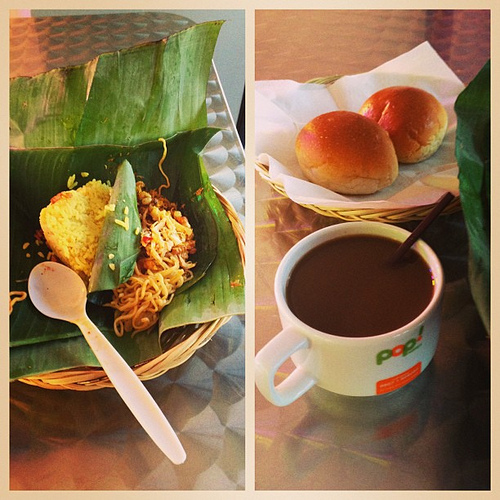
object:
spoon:
[28, 261, 186, 463]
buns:
[293, 109, 399, 196]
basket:
[254, 74, 467, 226]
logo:
[375, 329, 429, 367]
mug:
[258, 221, 444, 411]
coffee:
[287, 231, 435, 339]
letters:
[375, 342, 391, 369]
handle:
[254, 328, 314, 415]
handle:
[80, 323, 186, 464]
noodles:
[111, 176, 200, 333]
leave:
[8, 20, 221, 154]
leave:
[10, 128, 221, 350]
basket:
[14, 176, 243, 392]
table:
[9, 173, 492, 493]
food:
[45, 262, 55, 275]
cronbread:
[37, 181, 117, 273]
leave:
[10, 166, 248, 383]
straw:
[399, 193, 454, 257]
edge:
[10, 1, 201, 11]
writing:
[378, 363, 425, 395]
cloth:
[256, 40, 483, 210]